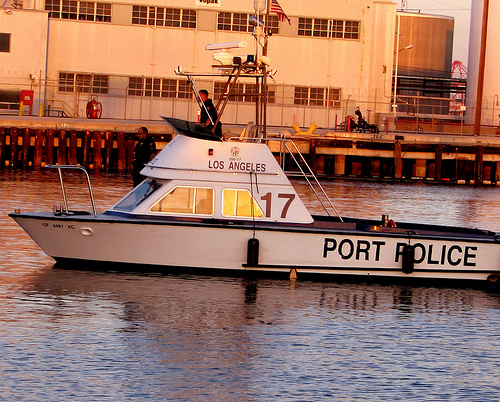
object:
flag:
[269, 0, 292, 25]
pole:
[262, 0, 270, 144]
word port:
[322, 236, 388, 262]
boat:
[6, 0, 499, 294]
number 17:
[259, 191, 297, 219]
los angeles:
[207, 159, 267, 173]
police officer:
[132, 125, 157, 188]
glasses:
[135, 132, 145, 135]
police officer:
[196, 88, 224, 141]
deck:
[137, 114, 298, 186]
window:
[192, 188, 217, 214]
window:
[220, 189, 236, 217]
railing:
[43, 163, 98, 216]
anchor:
[245, 237, 261, 269]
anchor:
[401, 243, 415, 274]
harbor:
[0, 110, 499, 190]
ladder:
[264, 131, 347, 223]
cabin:
[103, 175, 317, 223]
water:
[1, 170, 498, 401]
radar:
[203, 38, 251, 68]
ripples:
[320, 369, 400, 390]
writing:
[321, 236, 479, 267]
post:
[19, 100, 25, 116]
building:
[0, 0, 401, 130]